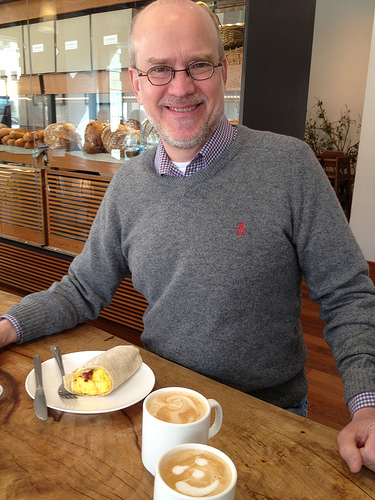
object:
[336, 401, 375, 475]
hand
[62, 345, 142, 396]
burrito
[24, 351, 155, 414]
plate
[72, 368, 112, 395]
egg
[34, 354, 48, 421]
knife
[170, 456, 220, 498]
happy face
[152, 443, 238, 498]
coffee mug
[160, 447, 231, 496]
drink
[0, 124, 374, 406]
sweater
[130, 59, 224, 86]
glasses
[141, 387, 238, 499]
two cups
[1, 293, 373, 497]
table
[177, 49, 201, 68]
ground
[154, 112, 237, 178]
plaid collar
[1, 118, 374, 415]
shirt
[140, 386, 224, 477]
cup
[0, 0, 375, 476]
gentleman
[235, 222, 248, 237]
logo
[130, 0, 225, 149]
face